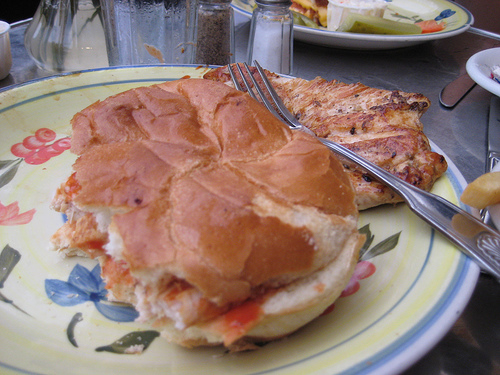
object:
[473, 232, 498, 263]
logo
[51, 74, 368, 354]
sandwich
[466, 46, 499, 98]
plate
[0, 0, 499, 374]
table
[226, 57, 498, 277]
fork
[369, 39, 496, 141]
table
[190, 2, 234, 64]
pepper shaker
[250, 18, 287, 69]
salt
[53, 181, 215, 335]
meat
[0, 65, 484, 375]
plate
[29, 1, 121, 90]
vase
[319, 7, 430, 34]
pickle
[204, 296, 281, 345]
sauce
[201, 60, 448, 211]
chicken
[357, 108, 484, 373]
edging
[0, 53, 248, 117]
edging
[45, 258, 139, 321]
flower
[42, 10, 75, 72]
stem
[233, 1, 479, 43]
plate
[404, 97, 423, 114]
browned bit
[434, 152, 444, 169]
browned bit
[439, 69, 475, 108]
knife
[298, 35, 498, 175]
edge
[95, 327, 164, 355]
pattern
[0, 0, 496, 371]
restaurant